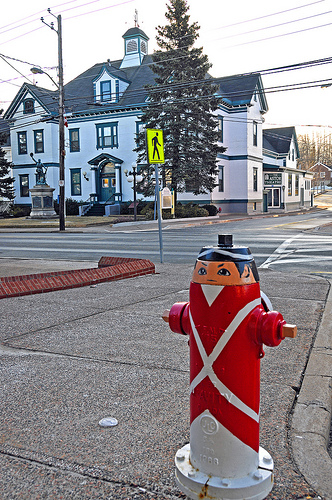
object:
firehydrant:
[160, 245, 295, 476]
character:
[184, 249, 263, 305]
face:
[184, 249, 276, 285]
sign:
[140, 123, 167, 174]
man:
[150, 134, 163, 162]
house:
[7, 19, 266, 212]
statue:
[24, 144, 57, 219]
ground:
[10, 208, 187, 245]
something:
[30, 148, 34, 160]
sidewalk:
[3, 223, 144, 237]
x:
[187, 314, 254, 432]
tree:
[142, 0, 224, 208]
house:
[307, 157, 332, 193]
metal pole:
[151, 164, 169, 265]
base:
[33, 189, 59, 219]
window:
[91, 119, 125, 150]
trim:
[94, 117, 118, 129]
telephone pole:
[54, 17, 72, 233]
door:
[88, 162, 130, 201]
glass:
[101, 177, 119, 187]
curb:
[289, 267, 330, 500]